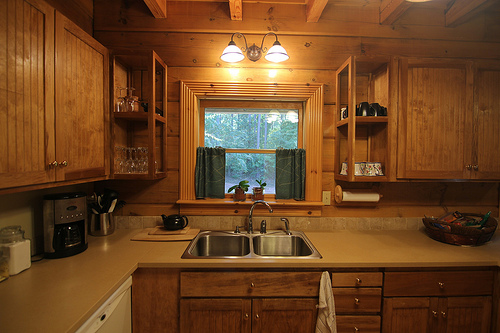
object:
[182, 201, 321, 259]
sink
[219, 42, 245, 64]
lights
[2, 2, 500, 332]
kitchen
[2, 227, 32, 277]
jar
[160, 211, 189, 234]
teapot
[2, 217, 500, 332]
counter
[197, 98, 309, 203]
window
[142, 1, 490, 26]
beams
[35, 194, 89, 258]
coffee maker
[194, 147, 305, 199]
curtains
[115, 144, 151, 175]
glasses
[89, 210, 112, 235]
container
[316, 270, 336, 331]
towel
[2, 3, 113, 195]
cabinets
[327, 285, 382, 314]
row of drawers